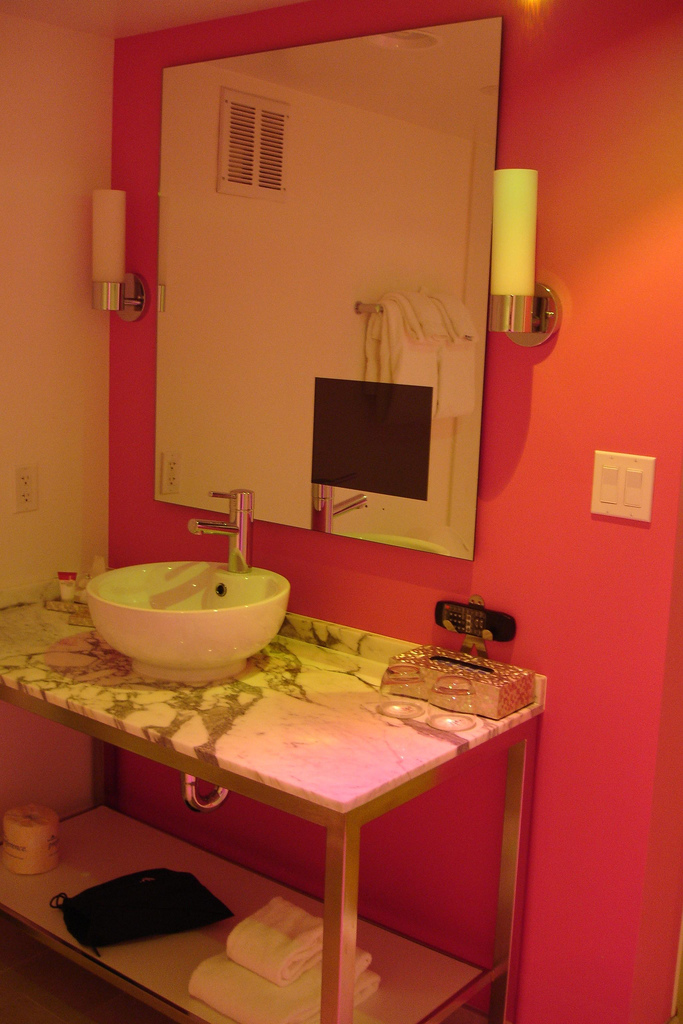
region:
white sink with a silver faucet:
[81, 483, 299, 682]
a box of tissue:
[384, 640, 544, 723]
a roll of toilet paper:
[0, 800, 62, 875]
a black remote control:
[436, 598, 517, 643]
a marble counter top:
[0, 564, 547, 816]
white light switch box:
[592, 447, 653, 527]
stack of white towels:
[186, 888, 379, 1021]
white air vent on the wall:
[207, 88, 298, 198]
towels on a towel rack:
[349, 284, 482, 420]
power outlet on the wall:
[13, 462, 41, 515]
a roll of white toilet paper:
[3, 802, 67, 883]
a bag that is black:
[38, 878, 214, 941]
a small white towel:
[228, 899, 316, 980]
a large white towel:
[194, 952, 360, 1022]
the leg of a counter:
[308, 837, 374, 1015]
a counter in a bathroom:
[0, 539, 546, 820]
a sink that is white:
[91, 545, 286, 677]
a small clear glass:
[371, 659, 429, 726]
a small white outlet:
[18, 474, 50, 518]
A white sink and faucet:
[86, 490, 293, 686]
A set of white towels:
[192, 894, 322, 1021]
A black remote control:
[434, 591, 517, 640]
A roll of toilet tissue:
[1, 803, 63, 877]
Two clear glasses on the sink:
[378, 663, 478, 720]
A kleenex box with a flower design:
[393, 650, 531, 712]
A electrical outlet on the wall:
[10, 464, 41, 514]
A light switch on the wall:
[588, 452, 661, 521]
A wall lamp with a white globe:
[90, 188, 147, 319]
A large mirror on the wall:
[158, 20, 505, 562]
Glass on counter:
[379, 663, 423, 719]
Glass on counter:
[425, 673, 479, 729]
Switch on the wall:
[592, 448, 659, 524]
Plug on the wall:
[6, 460, 46, 515]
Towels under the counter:
[185, 894, 380, 1022]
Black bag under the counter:
[48, 866, 234, 956]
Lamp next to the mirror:
[91, 187, 150, 318]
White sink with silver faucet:
[86, 488, 288, 684]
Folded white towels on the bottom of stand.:
[202, 885, 389, 1021]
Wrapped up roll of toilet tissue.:
[3, 789, 57, 867]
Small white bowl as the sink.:
[78, 547, 298, 679]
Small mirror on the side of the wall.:
[292, 368, 436, 516]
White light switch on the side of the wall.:
[585, 448, 655, 529]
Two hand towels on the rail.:
[351, 257, 481, 424]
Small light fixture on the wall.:
[87, 180, 153, 320]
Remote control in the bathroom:
[415, 591, 530, 638]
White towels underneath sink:
[176, 871, 390, 1020]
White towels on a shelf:
[204, 876, 380, 1020]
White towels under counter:
[197, 890, 373, 1020]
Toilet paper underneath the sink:
[3, 799, 78, 879]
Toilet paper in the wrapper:
[7, 801, 72, 872]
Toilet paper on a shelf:
[4, 802, 82, 886]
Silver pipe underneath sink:
[162, 773, 245, 818]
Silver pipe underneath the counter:
[180, 776, 231, 811]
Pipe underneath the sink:
[173, 773, 242, 818]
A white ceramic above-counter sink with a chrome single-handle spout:
[73, 484, 287, 684]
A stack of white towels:
[178, 888, 387, 1018]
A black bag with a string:
[28, 858, 240, 957]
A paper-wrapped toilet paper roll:
[2, 790, 63, 874]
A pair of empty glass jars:
[373, 651, 479, 733]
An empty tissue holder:
[377, 642, 535, 719]